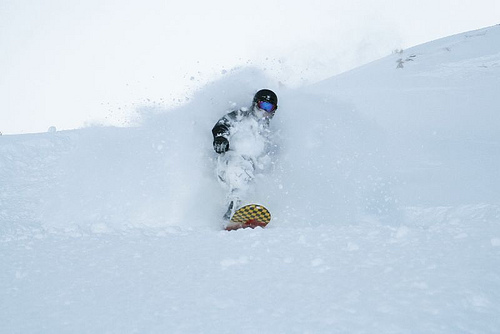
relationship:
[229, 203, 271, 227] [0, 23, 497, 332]
board buried in snow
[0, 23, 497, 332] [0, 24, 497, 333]
snow is on ground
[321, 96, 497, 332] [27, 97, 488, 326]
snow is on ground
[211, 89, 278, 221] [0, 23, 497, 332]
man is covered in snow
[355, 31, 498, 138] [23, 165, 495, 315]
mountain is covered in snow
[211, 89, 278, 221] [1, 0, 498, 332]
man is on hill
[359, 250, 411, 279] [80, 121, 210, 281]
snow on hillside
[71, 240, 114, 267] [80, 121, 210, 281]
snow on hillside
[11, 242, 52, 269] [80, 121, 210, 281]
snow on hillside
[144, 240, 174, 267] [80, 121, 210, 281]
snow on hillside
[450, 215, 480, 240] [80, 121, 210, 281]
snow on hillside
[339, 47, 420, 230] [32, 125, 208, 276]
white snow on hillside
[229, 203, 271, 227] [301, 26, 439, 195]
board on slope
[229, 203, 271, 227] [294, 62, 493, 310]
board on slope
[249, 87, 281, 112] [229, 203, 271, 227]
helmet on board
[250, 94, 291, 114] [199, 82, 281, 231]
goggles on snowboarder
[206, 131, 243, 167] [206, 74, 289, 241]
gloves on snowboarder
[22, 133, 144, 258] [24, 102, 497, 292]
snow on slopes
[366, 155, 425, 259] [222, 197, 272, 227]
snow kicked up by board